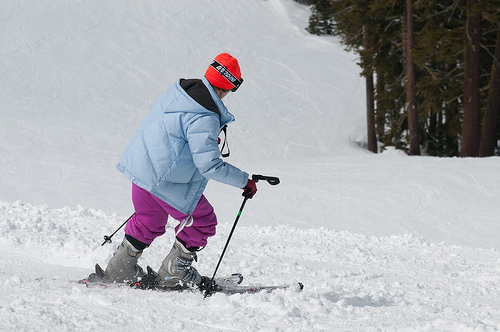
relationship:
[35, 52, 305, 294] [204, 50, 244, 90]
person wearing hat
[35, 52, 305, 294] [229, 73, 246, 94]
person wearing goggles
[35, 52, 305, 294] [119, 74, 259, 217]
person wearing jacket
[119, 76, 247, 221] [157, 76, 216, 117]
jacket has hood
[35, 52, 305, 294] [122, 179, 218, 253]
person wearing pants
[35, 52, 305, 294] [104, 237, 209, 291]
person wearing boots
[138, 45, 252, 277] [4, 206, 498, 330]
person skiing down a hill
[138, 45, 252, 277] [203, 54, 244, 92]
person wearing a hat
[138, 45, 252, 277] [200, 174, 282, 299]
person holding ski pole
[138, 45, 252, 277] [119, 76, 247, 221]
person wearing a jacket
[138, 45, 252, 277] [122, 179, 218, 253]
person wearing a pants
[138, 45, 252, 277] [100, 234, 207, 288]
person wearing boots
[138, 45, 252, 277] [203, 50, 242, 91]
person wearing a beanie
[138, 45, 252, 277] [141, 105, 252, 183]
person wearing a jacket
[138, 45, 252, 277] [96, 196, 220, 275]
person wearing pants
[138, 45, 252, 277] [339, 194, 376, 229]
person on snow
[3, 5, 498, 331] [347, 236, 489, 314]
snow covered ground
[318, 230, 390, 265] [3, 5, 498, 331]
ground covered snow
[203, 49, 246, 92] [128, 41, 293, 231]
head of person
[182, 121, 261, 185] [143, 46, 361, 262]
arm of person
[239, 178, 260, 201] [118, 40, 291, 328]
hand of person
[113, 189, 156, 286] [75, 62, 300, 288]
leg of person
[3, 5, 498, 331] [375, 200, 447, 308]
snow on ground